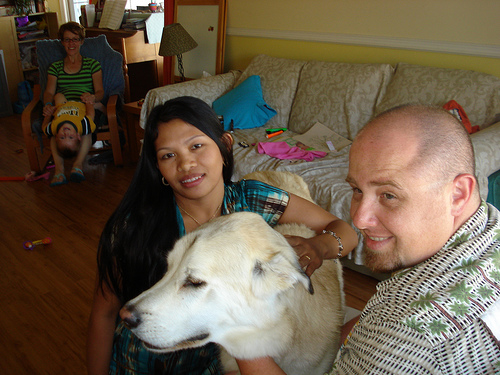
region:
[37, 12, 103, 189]
Woman sitting with child in her lap.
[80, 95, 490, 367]
Man and woman with a dog.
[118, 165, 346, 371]
White dog being petted.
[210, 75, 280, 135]
Blue pillow on sofa.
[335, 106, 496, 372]
Bald man wearing shirt with palm trees.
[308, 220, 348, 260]
Silver bracelet worn by a woman.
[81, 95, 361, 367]
Woman with black hair.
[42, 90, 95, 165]
Child wearing yellow and black shirt.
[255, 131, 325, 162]
Pink cloth on sofa.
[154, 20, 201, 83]
Brown lamp on side table.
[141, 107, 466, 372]
two people holding dog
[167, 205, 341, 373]
dog is white and large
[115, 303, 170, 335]
dog has black nose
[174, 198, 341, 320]
dog has white ears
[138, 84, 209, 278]
woman has dark hair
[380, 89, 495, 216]
man has little hair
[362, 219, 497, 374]
man has green and white shirt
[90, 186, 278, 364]
woman has blue checked shirt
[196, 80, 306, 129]
blue pillow on sofa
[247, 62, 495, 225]
sofa is gold and white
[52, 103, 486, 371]
a dog that is inside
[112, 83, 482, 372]
a lab is inside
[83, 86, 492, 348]
two people sitting on the floor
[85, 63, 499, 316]
two people sitting around a dog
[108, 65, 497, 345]
two people sitting around a lab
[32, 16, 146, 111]
a woman with glasses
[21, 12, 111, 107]
a woman wearing a green shirt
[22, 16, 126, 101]
a woman with short hair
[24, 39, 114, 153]
a woman with a toddler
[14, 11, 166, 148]
a toddler and a woman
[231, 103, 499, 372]
Man petting a dog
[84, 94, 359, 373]
Woman petting a dog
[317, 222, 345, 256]
Bracelet on the woman's wrist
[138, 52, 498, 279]
Couch in the living room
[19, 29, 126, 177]
Rocking chair in the living room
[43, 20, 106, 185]
Woman sitting on the rocking chair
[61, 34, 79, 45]
Glasses on the woman's face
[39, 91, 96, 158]
Child on the woman's lap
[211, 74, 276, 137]
Pillow on the couch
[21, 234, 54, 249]
Toy on the floor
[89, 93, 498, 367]
Man and woman with dog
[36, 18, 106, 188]
Woman with child upside down on her lap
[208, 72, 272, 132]
Blue pillow on sofa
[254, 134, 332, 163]
Piece of pink cloth on sofa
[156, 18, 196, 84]
Lamp to left of sofa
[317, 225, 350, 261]
Bracelet on woman's left wrist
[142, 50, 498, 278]
White sofa against the wall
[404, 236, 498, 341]
Palm trees on man's shirt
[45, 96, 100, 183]
Child in yellow shirt hanging upside down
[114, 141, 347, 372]
Big white dog